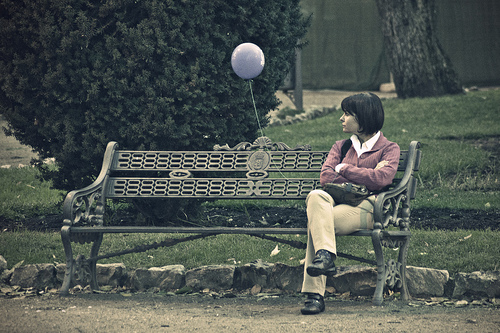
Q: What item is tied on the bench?
A: Balloon.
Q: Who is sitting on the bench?
A: A woman.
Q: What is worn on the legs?
A: A pant.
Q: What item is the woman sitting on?
A: A bench.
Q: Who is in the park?
A: A woman.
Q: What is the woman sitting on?
A: A bench.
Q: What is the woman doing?
A: Sitting.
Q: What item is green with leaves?
A: A tree.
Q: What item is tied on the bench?
A: A balloon.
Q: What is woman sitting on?
A: Park bench.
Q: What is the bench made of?
A: Metal.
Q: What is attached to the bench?
A: A balloon.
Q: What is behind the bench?
A: A large bush.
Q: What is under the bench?
A: Rocks.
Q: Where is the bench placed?
A: In a park.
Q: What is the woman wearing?
A: A pink sweater.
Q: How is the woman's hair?
A: Short.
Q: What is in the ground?
A: Legs.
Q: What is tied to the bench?
A: A ballon.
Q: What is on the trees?
A: Leaves.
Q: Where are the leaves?
A: On the tree.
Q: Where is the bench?
A: On the sidwalk.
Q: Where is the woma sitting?
A: On the bench.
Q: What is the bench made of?
A: Metal.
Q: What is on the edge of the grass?
A: Rocks.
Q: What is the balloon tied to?
A: Bench.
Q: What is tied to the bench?
A: A balloon.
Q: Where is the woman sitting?
A: On the bench.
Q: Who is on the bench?
A: The woman.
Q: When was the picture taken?
A: Daytime.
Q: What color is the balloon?
A: Purple.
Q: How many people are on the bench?
A: One.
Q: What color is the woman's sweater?
A: Red.